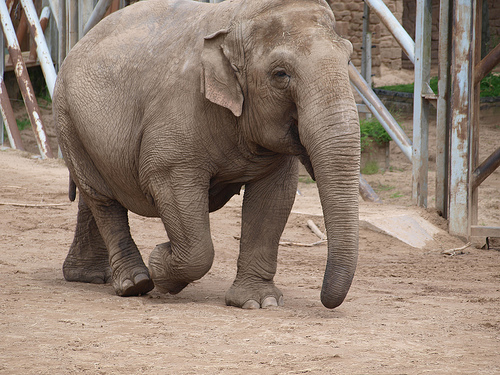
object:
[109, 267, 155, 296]
nails hoof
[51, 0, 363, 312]
elephant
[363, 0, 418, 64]
pole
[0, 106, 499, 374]
dirt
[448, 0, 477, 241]
metal pole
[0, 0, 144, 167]
fence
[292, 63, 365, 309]
trunk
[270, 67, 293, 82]
eye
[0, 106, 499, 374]
ground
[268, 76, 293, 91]
wrinkle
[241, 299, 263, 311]
nail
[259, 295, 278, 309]
nail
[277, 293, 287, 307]
nail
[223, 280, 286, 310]
hoof